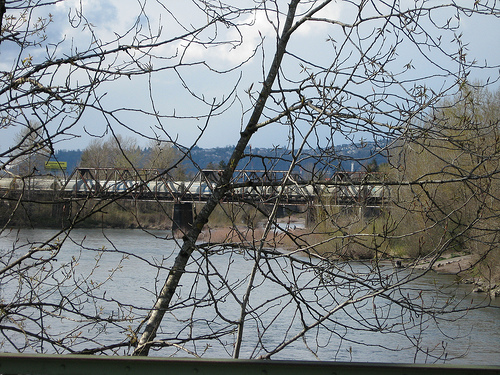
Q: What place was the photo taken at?
A: It was taken at the river.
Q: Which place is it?
A: It is a river.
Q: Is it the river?
A: Yes, it is the river.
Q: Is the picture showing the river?
A: Yes, it is showing the river.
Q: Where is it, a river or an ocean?
A: It is a river.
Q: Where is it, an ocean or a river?
A: It is a river.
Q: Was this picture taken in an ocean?
A: No, the picture was taken in a river.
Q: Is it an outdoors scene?
A: Yes, it is outdoors.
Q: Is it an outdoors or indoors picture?
A: It is outdoors.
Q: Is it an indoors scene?
A: No, it is outdoors.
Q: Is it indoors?
A: No, it is outdoors.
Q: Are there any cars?
A: No, there are no cars.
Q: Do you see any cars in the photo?
A: No, there are no cars.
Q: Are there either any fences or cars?
A: No, there are no cars or fences.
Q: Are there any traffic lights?
A: No, there are no traffic lights.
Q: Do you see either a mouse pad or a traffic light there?
A: No, there are no traffic lights or mouse pads.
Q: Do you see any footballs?
A: No, there are no footballs.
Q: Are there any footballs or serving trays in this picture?
A: No, there are no footballs or serving trays.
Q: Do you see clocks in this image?
A: No, there are no clocks.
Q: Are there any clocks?
A: No, there are no clocks.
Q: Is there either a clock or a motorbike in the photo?
A: No, there are no clocks or motorcycles.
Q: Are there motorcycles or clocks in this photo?
A: No, there are no clocks or motorcycles.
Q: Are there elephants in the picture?
A: No, there are no elephants.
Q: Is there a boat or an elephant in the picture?
A: No, there are no elephants or boats.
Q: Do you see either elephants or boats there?
A: No, there are no elephants or boats.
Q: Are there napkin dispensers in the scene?
A: No, there are no napkin dispensers.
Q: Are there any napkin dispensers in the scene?
A: No, there are no napkin dispensers.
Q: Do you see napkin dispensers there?
A: No, there are no napkin dispensers.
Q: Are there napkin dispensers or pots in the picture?
A: No, there are no napkin dispensers or pots.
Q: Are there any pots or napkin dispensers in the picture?
A: No, there are no napkin dispensers or pots.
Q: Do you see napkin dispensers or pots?
A: No, there are no napkin dispensers or pots.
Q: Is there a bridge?
A: Yes, there is a bridge.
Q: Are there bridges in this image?
A: Yes, there is a bridge.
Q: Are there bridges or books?
A: Yes, there is a bridge.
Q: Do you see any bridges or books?
A: Yes, there is a bridge.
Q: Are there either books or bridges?
A: Yes, there is a bridge.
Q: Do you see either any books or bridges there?
A: Yes, there is a bridge.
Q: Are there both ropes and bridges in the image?
A: No, there is a bridge but no ropes.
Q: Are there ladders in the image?
A: No, there are no ladders.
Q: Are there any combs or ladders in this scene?
A: No, there are no ladders or combs.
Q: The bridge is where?
A: The bridge is in the river.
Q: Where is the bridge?
A: The bridge is in the river.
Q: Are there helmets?
A: No, there are no helmets.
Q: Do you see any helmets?
A: No, there are no helmets.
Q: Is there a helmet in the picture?
A: No, there are no helmets.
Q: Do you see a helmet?
A: No, there are no helmets.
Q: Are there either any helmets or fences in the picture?
A: No, there are no helmets or fences.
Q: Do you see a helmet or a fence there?
A: No, there are no helmets or fences.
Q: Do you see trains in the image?
A: Yes, there is a train.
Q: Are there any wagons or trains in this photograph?
A: Yes, there is a train.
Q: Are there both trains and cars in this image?
A: No, there is a train but no cars.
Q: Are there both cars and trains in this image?
A: No, there is a train but no cars.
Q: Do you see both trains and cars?
A: No, there is a train but no cars.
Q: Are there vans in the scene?
A: No, there are no vans.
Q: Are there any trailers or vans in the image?
A: No, there are no vans or trailers.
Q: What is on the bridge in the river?
A: The train is on the bridge.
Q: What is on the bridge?
A: The train is on the bridge.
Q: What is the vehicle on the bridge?
A: The vehicle is a train.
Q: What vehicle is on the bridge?
A: The vehicle is a train.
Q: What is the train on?
A: The train is on the bridge.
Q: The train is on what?
A: The train is on the bridge.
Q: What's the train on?
A: The train is on the bridge.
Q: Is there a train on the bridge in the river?
A: Yes, there is a train on the bridge.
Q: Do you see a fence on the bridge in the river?
A: No, there is a train on the bridge.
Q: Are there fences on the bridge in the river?
A: No, there is a train on the bridge.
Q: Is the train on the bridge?
A: Yes, the train is on the bridge.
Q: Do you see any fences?
A: No, there are no fences.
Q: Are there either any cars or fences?
A: No, there are no fences or cars.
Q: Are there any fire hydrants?
A: No, there are no fire hydrants.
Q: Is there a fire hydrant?
A: No, there are no fire hydrants.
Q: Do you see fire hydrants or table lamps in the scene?
A: No, there are no fire hydrants or table lamps.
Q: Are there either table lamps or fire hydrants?
A: No, there are no fire hydrants or table lamps.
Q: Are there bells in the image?
A: No, there are no bells.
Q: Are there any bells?
A: No, there are no bells.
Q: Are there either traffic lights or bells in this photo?
A: No, there are no bells or traffic lights.